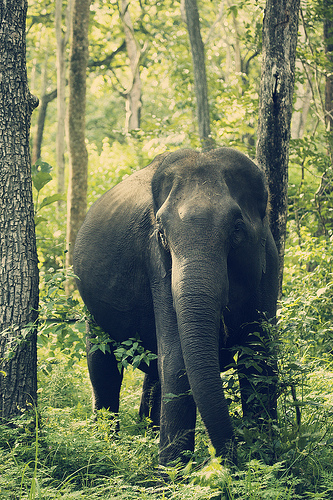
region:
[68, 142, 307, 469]
A large grey elephant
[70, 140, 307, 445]
A big elephant standing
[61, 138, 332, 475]
An elephant in the woods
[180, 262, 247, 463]
The trunk of the elephant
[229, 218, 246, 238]
The eye of the elephant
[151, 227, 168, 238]
The eye of the elephant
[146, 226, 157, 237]
The eyelashes of the elephant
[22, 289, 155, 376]
A bunch of green leaves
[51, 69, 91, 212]
Two tall trees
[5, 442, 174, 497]
A large green bush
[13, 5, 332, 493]
an elephant is standing in a jungle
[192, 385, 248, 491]
the elephant's trunk is in the bushes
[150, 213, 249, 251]
the eyes are open on the elephant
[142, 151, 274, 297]
the elephant has small ears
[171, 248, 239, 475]
the truck of the elephant has grooves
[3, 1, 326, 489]
the gray elephant is wondering in the woods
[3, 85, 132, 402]
a rough tree trunk is next to the animal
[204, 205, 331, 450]
bushes are near the elephant's head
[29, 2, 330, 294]
different trees are behind the elephant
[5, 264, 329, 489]
grasses, ferns, and shrubs are in the woods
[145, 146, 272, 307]
face of grey elephant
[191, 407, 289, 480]
elephant trunk in greenery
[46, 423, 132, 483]
scene of green leaves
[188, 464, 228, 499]
ferns in direct sunlight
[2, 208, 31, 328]
brown tree bark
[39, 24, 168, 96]
daylight forest scene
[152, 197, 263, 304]
elephant looking off into the distance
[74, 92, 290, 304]
elephant standing in forest during daytime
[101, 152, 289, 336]
front view of large grey elephant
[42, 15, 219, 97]
image of numerous trees in sunlight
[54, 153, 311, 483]
Elephant in the jungle.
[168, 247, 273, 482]
Trunk of the elephant.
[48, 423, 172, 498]
Grass on the ground.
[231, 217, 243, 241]
Eye of the elephant.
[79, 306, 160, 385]
Leaves rubbing the elephant.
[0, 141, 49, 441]
Tree beside the elephant.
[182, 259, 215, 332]
Wrinkles on elephant trunk.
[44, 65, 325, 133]
Forest in the background.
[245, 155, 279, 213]
Hair on the elephant.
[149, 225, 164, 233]
Eyelashes of the elephant.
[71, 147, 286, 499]
large elephant standing in the jungle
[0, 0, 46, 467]
large tree standing next to elephant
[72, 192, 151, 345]
big round belly of elephant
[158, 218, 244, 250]
eyesof elephant look straight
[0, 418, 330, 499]
green grass and weeds on ground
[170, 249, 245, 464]
elephant long large trunk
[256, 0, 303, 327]
large tree behind elephant in jungle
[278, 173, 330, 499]
bushes and trees behind elephant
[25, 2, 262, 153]
lot of trees and woods back behind elephant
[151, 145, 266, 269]
large head of elephant